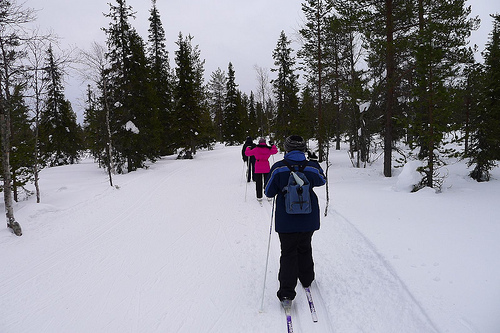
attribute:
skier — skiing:
[242, 136, 278, 199]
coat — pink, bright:
[245, 144, 278, 175]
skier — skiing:
[263, 132, 328, 306]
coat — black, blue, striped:
[265, 150, 328, 231]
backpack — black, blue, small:
[282, 159, 312, 215]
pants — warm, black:
[276, 231, 316, 300]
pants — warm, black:
[253, 172, 272, 197]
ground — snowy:
[1, 127, 498, 330]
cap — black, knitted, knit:
[282, 134, 307, 153]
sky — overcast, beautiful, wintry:
[0, 1, 498, 121]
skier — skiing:
[241, 135, 257, 181]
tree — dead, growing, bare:
[81, 43, 126, 187]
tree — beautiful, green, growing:
[142, 1, 180, 154]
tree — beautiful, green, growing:
[171, 30, 201, 154]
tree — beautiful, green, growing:
[35, 44, 86, 165]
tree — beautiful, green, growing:
[222, 63, 244, 146]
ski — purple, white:
[281, 309, 295, 332]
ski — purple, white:
[303, 286, 319, 323]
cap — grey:
[258, 137, 267, 144]